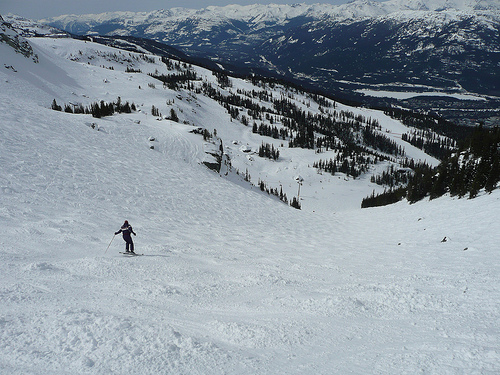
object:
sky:
[0, 0, 354, 16]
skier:
[113, 219, 138, 254]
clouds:
[0, 0, 355, 15]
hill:
[31, 0, 499, 151]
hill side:
[42, 0, 499, 48]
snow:
[36, 0, 500, 35]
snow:
[0, 13, 499, 375]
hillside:
[0, 7, 499, 375]